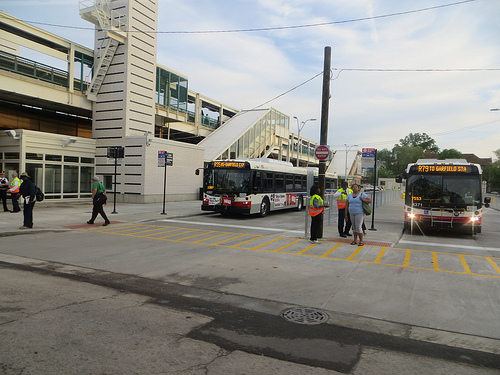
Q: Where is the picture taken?
A: Bus stop.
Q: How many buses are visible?
A: 2.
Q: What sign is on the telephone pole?
A: Do not enter.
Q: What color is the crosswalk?
A: Yellow.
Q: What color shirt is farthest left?
A: White.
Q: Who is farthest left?
A: Police officer.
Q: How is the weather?
A: Cloudy.